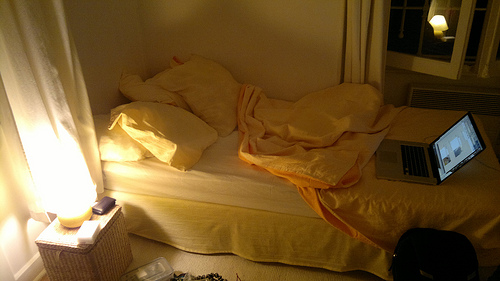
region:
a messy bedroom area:
[32, 24, 484, 268]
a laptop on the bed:
[346, 96, 483, 196]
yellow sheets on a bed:
[139, 40, 374, 217]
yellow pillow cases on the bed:
[110, 52, 237, 163]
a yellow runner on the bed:
[121, 180, 373, 270]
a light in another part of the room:
[371, 2, 479, 69]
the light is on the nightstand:
[32, 122, 120, 237]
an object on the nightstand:
[87, 191, 125, 215]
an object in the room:
[384, 210, 499, 268]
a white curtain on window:
[3, 9, 113, 202]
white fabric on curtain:
[40, 168, 63, 200]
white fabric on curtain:
[33, 126, 61, 146]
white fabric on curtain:
[28, 110, 47, 130]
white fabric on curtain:
[11, 87, 32, 115]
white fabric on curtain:
[38, 98, 80, 134]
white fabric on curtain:
[25, 84, 54, 101]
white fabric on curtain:
[31, 60, 74, 95]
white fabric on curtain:
[70, 97, 97, 124]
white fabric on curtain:
[6, 53, 35, 93]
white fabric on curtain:
[51, 36, 80, 75]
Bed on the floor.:
[71, 29, 318, 274]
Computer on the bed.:
[361, 95, 498, 189]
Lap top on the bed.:
[368, 102, 481, 200]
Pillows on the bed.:
[90, 39, 297, 241]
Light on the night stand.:
[18, 140, 131, 268]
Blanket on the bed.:
[203, 24, 392, 231]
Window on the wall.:
[384, 18, 494, 100]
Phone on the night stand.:
[79, 184, 132, 254]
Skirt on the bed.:
[159, 179, 268, 276]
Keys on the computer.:
[371, 117, 462, 212]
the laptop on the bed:
[375, 123, 486, 184]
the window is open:
[384, 2, 466, 71]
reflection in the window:
[424, 11, 458, 42]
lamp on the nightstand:
[45, 156, 105, 212]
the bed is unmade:
[134, 43, 389, 250]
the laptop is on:
[376, 116, 479, 200]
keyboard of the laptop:
[401, 138, 428, 181]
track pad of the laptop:
[383, 147, 394, 167]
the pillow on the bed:
[109, 101, 199, 171]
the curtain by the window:
[344, 4, 392, 87]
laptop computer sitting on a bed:
[373, 115, 483, 186]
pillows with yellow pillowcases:
[103, 55, 225, 169]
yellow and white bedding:
[126, 81, 383, 236]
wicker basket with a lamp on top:
[39, 165, 130, 279]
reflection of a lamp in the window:
[428, 13, 451, 40]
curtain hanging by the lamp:
[0, 5, 93, 175]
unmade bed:
[128, 65, 363, 201]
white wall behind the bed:
[78, 0, 330, 52]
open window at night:
[386, 0, 470, 85]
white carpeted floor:
[168, 257, 248, 268]